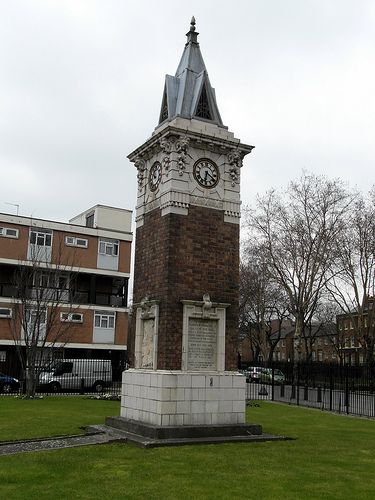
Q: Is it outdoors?
A: Yes, it is outdoors.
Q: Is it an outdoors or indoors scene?
A: It is outdoors.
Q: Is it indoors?
A: No, it is outdoors.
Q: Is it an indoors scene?
A: No, it is outdoors.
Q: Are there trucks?
A: No, there are no trucks.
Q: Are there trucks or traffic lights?
A: No, there are no trucks or traffic lights.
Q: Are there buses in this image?
A: No, there are no buses.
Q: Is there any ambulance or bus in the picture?
A: No, there are no buses or ambulances.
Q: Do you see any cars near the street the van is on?
A: Yes, there is a car near the street.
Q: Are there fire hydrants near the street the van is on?
A: No, there is a car near the street.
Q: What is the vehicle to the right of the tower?
A: The vehicle is a car.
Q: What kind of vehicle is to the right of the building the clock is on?
A: The vehicle is a car.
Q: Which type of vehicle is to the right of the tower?
A: The vehicle is a car.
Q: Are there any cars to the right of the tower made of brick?
A: Yes, there is a car to the right of the tower.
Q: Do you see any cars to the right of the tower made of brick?
A: Yes, there is a car to the right of the tower.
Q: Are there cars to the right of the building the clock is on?
A: Yes, there is a car to the right of the tower.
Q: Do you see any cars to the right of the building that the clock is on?
A: Yes, there is a car to the right of the tower.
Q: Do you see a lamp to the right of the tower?
A: No, there is a car to the right of the tower.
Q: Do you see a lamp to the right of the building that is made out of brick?
A: No, there is a car to the right of the tower.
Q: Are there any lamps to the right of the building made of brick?
A: No, there is a car to the right of the tower.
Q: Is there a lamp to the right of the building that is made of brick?
A: No, there is a car to the right of the tower.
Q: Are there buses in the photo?
A: No, there are no buses.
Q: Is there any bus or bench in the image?
A: No, there are no buses or benches.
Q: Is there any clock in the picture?
A: Yes, there is a clock.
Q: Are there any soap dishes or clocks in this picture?
A: Yes, there is a clock.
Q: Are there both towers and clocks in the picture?
A: Yes, there are both a clock and a tower.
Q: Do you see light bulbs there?
A: No, there are no light bulbs.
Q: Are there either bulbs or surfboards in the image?
A: No, there are no bulbs or surfboards.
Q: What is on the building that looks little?
A: The clock is on the tower.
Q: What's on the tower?
A: The clock is on the tower.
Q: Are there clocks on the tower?
A: Yes, there is a clock on the tower.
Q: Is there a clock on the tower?
A: Yes, there is a clock on the tower.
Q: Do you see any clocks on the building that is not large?
A: Yes, there is a clock on the tower.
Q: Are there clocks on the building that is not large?
A: Yes, there is a clock on the tower.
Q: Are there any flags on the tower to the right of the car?
A: No, there is a clock on the tower.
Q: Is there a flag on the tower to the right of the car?
A: No, there is a clock on the tower.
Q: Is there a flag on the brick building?
A: No, there is a clock on the tower.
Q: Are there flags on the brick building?
A: No, there is a clock on the tower.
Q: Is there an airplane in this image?
A: No, there are no airplanes.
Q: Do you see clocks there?
A: Yes, there is a clock.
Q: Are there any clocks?
A: Yes, there is a clock.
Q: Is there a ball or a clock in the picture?
A: Yes, there is a clock.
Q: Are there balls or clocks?
A: Yes, there is a clock.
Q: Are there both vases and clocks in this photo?
A: No, there is a clock but no vases.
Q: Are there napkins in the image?
A: No, there are no napkins.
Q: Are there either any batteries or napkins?
A: No, there are no napkins or batteries.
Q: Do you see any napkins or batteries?
A: No, there are no napkins or batteries.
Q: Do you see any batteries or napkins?
A: No, there are no napkins or batteries.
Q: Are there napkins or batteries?
A: No, there are no napkins or batteries.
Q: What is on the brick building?
A: The clock is on the tower.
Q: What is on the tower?
A: The clock is on the tower.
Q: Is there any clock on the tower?
A: Yes, there is a clock on the tower.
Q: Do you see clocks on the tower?
A: Yes, there is a clock on the tower.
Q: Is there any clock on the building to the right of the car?
A: Yes, there is a clock on the tower.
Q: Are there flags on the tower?
A: No, there is a clock on the tower.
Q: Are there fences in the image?
A: Yes, there is a fence.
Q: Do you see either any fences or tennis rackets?
A: Yes, there is a fence.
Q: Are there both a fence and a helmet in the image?
A: No, there is a fence but no helmets.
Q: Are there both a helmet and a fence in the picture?
A: No, there is a fence but no helmets.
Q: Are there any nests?
A: No, there are no nests.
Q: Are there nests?
A: No, there are no nests.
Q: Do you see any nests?
A: No, there are no nests.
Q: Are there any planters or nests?
A: No, there are no nests or planters.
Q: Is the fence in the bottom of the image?
A: Yes, the fence is in the bottom of the image.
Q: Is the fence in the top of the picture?
A: No, the fence is in the bottom of the image.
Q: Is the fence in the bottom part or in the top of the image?
A: The fence is in the bottom of the image.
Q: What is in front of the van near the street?
A: The fence is in front of the van.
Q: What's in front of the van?
A: The fence is in front of the van.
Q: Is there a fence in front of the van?
A: Yes, there is a fence in front of the van.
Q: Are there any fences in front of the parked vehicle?
A: Yes, there is a fence in front of the van.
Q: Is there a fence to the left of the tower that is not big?
A: Yes, there is a fence to the left of the tower.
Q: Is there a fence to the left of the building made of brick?
A: Yes, there is a fence to the left of the tower.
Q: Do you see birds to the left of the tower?
A: No, there is a fence to the left of the tower.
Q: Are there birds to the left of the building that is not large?
A: No, there is a fence to the left of the tower.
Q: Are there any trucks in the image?
A: No, there are no trucks.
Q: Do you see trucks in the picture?
A: No, there are no trucks.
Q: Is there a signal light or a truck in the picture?
A: No, there are no trucks or traffic lights.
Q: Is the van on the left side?
A: Yes, the van is on the left of the image.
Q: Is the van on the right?
A: No, the van is on the left of the image.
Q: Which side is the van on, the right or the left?
A: The van is on the left of the image.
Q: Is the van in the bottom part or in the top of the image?
A: The van is in the bottom of the image.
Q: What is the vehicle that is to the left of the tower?
A: The vehicle is a van.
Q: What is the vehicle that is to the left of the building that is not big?
A: The vehicle is a van.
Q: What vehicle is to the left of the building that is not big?
A: The vehicle is a van.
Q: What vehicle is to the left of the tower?
A: The vehicle is a van.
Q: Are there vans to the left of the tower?
A: Yes, there is a van to the left of the tower.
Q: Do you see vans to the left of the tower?
A: Yes, there is a van to the left of the tower.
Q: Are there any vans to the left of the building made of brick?
A: Yes, there is a van to the left of the tower.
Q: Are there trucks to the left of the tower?
A: No, there is a van to the left of the tower.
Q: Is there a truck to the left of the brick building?
A: No, there is a van to the left of the tower.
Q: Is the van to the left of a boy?
A: No, the van is to the left of the tower.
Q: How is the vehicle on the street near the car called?
A: The vehicle is a van.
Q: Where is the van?
A: The van is on the street.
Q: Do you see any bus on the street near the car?
A: No, there is a van on the street.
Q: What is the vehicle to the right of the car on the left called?
A: The vehicle is a van.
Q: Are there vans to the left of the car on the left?
A: No, the van is to the right of the car.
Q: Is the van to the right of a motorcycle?
A: No, the van is to the right of a car.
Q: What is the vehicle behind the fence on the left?
A: The vehicle is a van.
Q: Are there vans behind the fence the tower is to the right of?
A: Yes, there is a van behind the fence.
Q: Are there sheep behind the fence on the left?
A: No, there is a van behind the fence.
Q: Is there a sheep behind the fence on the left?
A: No, there is a van behind the fence.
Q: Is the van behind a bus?
A: No, the van is behind the fence.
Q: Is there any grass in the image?
A: Yes, there is grass.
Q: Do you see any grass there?
A: Yes, there is grass.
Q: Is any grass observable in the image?
A: Yes, there is grass.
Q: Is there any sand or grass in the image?
A: Yes, there is grass.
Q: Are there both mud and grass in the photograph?
A: No, there is grass but no mud.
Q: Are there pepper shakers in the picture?
A: No, there are no pepper shakers.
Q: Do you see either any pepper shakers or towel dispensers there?
A: No, there are no pepper shakers or towel dispensers.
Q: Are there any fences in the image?
A: Yes, there is a fence.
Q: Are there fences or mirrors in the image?
A: Yes, there is a fence.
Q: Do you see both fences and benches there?
A: No, there is a fence but no benches.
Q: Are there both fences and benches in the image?
A: No, there is a fence but no benches.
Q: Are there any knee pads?
A: No, there are no knee pads.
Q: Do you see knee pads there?
A: No, there are no knee pads.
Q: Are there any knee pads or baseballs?
A: No, there are no knee pads or baseballs.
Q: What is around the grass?
A: The fence is around the grass.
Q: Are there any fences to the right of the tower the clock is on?
A: Yes, there is a fence to the right of the tower.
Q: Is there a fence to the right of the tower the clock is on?
A: Yes, there is a fence to the right of the tower.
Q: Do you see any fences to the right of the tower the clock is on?
A: Yes, there is a fence to the right of the tower.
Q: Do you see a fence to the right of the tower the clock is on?
A: Yes, there is a fence to the right of the tower.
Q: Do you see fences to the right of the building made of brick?
A: Yes, there is a fence to the right of the tower.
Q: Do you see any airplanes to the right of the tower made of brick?
A: No, there is a fence to the right of the tower.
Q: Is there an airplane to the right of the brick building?
A: No, there is a fence to the right of the tower.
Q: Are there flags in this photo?
A: No, there are no flags.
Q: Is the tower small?
A: Yes, the tower is small.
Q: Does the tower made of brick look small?
A: Yes, the tower is small.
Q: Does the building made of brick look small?
A: Yes, the tower is small.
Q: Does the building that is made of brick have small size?
A: Yes, the tower is small.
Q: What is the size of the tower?
A: The tower is small.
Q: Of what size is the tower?
A: The tower is small.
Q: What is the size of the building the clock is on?
A: The tower is small.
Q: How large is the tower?
A: The tower is small.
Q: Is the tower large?
A: No, the tower is small.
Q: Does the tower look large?
A: No, the tower is small.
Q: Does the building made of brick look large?
A: No, the tower is small.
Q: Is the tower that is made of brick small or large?
A: The tower is small.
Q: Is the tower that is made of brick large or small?
A: The tower is small.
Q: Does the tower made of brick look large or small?
A: The tower is small.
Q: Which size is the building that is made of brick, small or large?
A: The tower is small.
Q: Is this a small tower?
A: Yes, this is a small tower.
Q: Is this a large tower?
A: No, this is a small tower.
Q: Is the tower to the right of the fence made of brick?
A: Yes, the tower is made of brick.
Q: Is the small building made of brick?
A: Yes, the tower is made of brick.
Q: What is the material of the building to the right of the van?
A: The tower is made of brick.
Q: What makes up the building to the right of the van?
A: The tower is made of brick.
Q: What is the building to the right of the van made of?
A: The tower is made of brick.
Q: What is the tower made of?
A: The tower is made of brick.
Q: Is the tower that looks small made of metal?
A: No, the tower is made of brick.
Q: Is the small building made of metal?
A: No, the tower is made of brick.